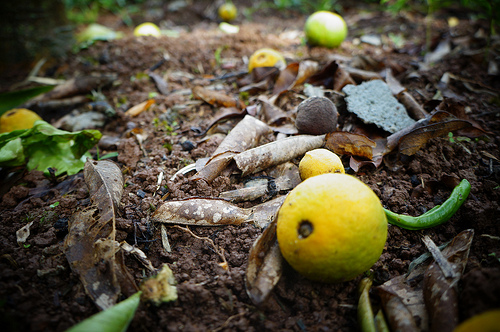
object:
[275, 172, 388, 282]
fruit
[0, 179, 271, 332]
ground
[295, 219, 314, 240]
stem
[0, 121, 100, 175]
leaf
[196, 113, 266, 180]
leaves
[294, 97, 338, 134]
lemon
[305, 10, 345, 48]
fruit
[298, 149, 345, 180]
fruit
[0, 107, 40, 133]
lemon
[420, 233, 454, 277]
stick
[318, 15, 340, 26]
light